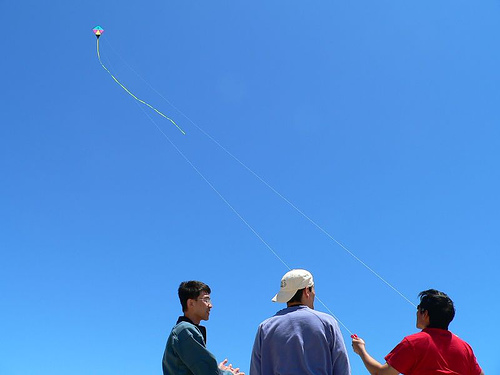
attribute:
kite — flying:
[92, 25, 188, 143]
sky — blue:
[1, 0, 496, 266]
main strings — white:
[97, 35, 423, 336]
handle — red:
[347, 329, 358, 346]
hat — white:
[273, 267, 316, 306]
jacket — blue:
[162, 313, 239, 373]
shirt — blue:
[248, 307, 353, 373]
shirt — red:
[383, 327, 484, 374]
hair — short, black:
[178, 281, 213, 311]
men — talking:
[160, 267, 490, 374]